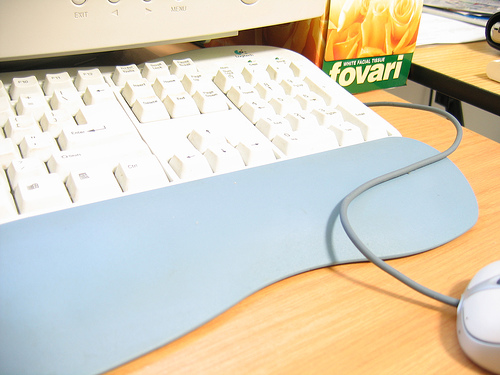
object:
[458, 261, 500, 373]
mouse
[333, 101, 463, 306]
cord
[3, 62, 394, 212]
keyboard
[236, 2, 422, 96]
box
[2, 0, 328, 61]
monitor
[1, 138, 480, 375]
pad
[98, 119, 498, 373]
table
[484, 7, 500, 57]
camera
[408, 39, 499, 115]
table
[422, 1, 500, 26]
notebook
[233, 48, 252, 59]
logo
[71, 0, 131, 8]
buttons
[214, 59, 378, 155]
number pad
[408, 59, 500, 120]
trim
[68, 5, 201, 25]
button labels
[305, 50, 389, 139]
edge